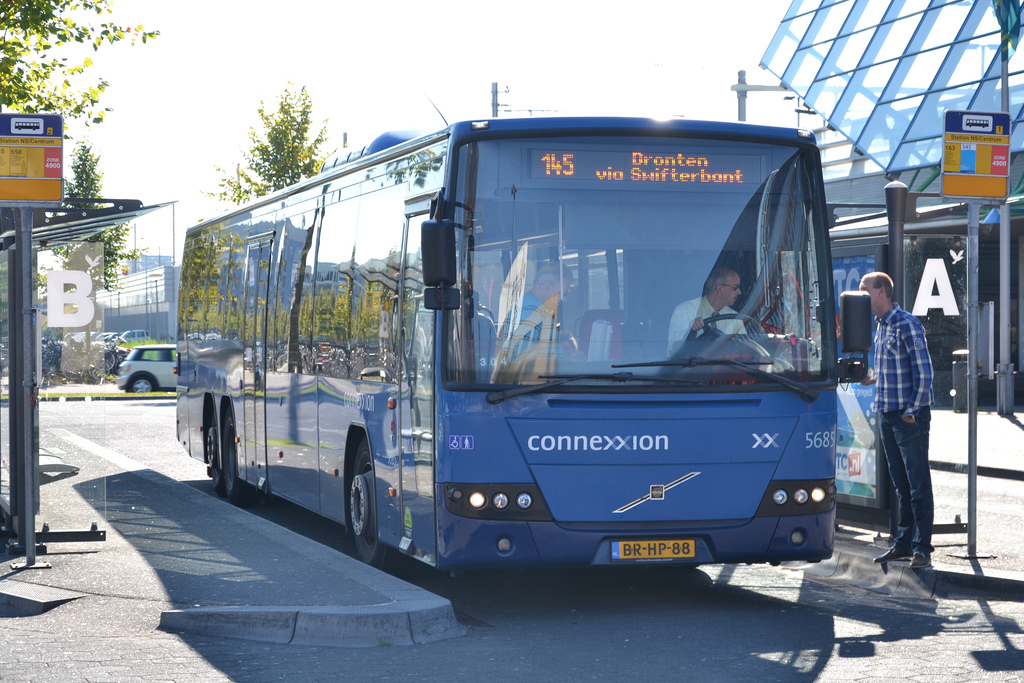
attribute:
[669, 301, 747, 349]
shirt — white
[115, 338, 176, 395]
vehicle — silver colored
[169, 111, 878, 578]
bus — blue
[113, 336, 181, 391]
car — parked, white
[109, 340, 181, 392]
car — white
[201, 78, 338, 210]
tree — green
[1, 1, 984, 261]
sky — white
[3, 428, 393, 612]
walkway — gray